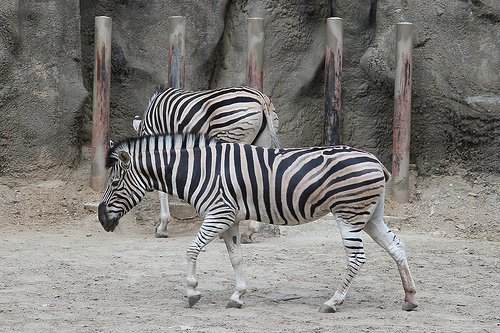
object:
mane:
[103, 130, 230, 170]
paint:
[322, 45, 343, 147]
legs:
[182, 206, 240, 309]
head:
[96, 136, 147, 234]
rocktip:
[354, 25, 394, 90]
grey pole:
[89, 14, 114, 192]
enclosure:
[0, 0, 500, 333]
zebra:
[134, 81, 284, 241]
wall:
[0, 0, 500, 189]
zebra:
[60, 101, 479, 321]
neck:
[140, 131, 208, 208]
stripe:
[138, 138, 152, 188]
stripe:
[175, 134, 188, 199]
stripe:
[162, 135, 167, 171]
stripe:
[154, 150, 166, 193]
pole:
[391, 21, 415, 206]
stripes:
[233, 143, 250, 221]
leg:
[153, 190, 172, 239]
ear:
[118, 150, 131, 166]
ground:
[3, 166, 500, 333]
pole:
[167, 15, 188, 90]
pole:
[322, 15, 345, 146]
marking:
[90, 43, 111, 154]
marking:
[167, 32, 186, 87]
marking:
[392, 51, 413, 184]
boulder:
[0, 0, 94, 183]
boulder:
[78, 0, 228, 148]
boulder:
[210, 0, 380, 157]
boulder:
[357, 0, 500, 178]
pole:
[245, 16, 266, 93]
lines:
[208, 110, 262, 132]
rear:
[204, 84, 280, 142]